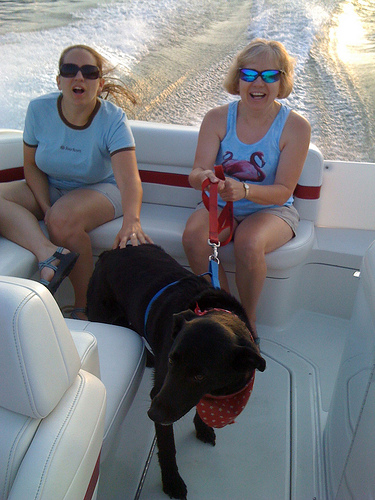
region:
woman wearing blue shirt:
[3, 37, 162, 254]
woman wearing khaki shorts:
[4, 30, 144, 240]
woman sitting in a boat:
[11, 42, 88, 297]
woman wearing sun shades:
[9, 35, 141, 240]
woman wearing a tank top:
[185, 35, 316, 265]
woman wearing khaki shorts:
[172, 36, 329, 257]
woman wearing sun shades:
[177, 28, 328, 262]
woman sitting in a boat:
[180, 27, 303, 267]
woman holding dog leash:
[184, 30, 327, 262]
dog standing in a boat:
[114, 282, 260, 498]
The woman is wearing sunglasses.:
[236, 65, 283, 85]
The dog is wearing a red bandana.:
[190, 368, 256, 428]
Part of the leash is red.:
[198, 162, 232, 242]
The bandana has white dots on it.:
[193, 364, 255, 427]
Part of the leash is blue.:
[198, 257, 225, 289]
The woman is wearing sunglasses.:
[58, 61, 100, 81]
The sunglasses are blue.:
[238, 67, 280, 82]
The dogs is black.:
[86, 241, 267, 498]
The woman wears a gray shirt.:
[22, 91, 135, 187]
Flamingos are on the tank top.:
[219, 145, 268, 178]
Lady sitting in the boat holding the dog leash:
[180, 26, 319, 313]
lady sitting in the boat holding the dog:
[1, 29, 217, 344]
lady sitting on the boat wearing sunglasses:
[190, 24, 322, 300]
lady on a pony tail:
[10, 25, 138, 266]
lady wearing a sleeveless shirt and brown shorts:
[178, 18, 329, 270]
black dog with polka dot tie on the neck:
[62, 236, 284, 498]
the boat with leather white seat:
[0, 114, 342, 333]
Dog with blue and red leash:
[115, 161, 284, 394]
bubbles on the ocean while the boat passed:
[21, 10, 358, 41]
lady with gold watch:
[203, 28, 317, 271]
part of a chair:
[74, 416, 93, 434]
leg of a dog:
[162, 450, 170, 468]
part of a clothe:
[223, 407, 236, 420]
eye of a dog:
[199, 374, 203, 377]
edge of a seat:
[52, 388, 75, 419]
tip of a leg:
[173, 481, 177, 484]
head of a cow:
[166, 395, 172, 408]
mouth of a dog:
[154, 414, 159, 416]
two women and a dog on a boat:
[5, 5, 367, 496]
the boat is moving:
[2, 11, 371, 478]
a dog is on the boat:
[85, 239, 274, 498]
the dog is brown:
[80, 239, 266, 498]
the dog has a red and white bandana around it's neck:
[75, 242, 272, 492]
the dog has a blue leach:
[82, 234, 286, 498]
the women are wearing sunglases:
[9, 37, 314, 332]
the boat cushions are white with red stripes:
[4, 127, 374, 496]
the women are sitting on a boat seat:
[2, 18, 325, 346]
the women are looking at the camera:
[7, 31, 312, 451]